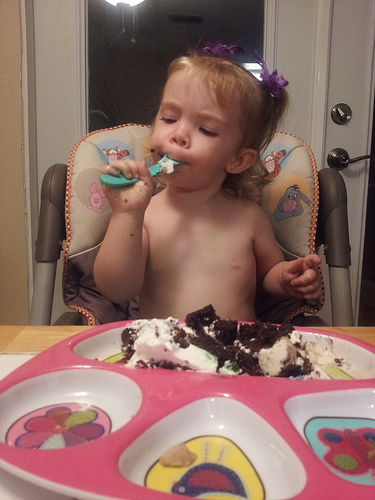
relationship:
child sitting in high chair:
[93, 42, 323, 328] [25, 122, 352, 325]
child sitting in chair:
[93, 42, 323, 328] [30, 122, 355, 328]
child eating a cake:
[93, 42, 323, 328] [111, 302, 359, 382]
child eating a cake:
[93, 42, 323, 328] [117, 301, 316, 376]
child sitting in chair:
[93, 42, 323, 328] [38, 126, 358, 327]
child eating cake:
[96, 61, 316, 302] [73, 303, 371, 478]